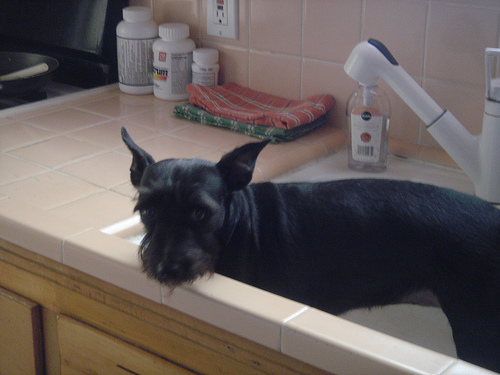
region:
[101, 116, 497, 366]
a dog in a sink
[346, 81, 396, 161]
a hand soap on a sink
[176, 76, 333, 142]
a couple of towels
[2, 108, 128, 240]
a cream color counter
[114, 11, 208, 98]
bottles on a counter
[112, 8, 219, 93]
white bottles on a counter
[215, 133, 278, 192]
a black dogs ear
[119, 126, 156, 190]
a black dog right ear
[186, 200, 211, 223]
a left eye of a dog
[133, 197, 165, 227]
a right eye of a dog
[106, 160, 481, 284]
dog in the sink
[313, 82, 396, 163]
bottle of soap on the sink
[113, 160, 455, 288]
black dog taking a bath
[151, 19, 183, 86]
bottle of vitamins on the counter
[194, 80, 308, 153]
two towels on a counter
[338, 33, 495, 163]
White plastic faucet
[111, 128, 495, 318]
Black dog in the sink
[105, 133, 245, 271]
Dog looking straight ahead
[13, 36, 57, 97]
Pot on the stove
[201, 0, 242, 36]
Plug on the wall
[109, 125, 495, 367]
a black dog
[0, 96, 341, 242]
a counter top tile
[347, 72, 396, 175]
a hand soap bottle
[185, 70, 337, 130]
a red and white tile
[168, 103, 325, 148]
a green and white tile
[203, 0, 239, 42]
part of a white wall outlet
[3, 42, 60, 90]
part of a black pan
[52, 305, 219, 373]
part of a brown cabinet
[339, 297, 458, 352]
part of a white sink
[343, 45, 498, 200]
a white kitchen faucet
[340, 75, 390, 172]
bottle of hand soap on the sink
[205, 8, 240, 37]
power outlet in the wall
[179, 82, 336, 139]
hand towels on the counter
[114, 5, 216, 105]
vitamins on the counter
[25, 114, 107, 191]
tiled counter top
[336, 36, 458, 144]
white removable faucet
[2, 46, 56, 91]
pan on the stove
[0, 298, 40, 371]
drawer below the counter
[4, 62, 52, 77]
wooden utensil in pan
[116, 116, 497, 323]
A black do in a sink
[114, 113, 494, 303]
A black dog ready to get a bath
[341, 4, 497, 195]
A white sink faucet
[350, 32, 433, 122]
Spray nozzle with a blue button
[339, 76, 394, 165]
A clear bottle of liquid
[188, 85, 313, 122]
An orange striped towel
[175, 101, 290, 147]
A green striped towel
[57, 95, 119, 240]
A beige tile counter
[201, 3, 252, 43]
A white recepticle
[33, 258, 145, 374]
Brown wooden cabinet